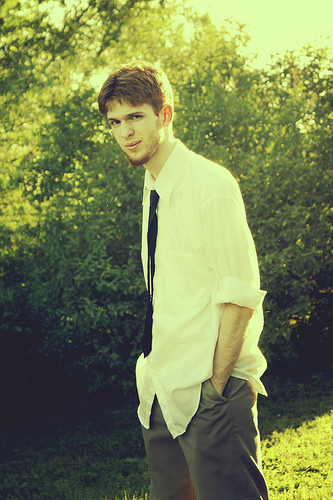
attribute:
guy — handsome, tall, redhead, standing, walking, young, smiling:
[98, 62, 269, 498]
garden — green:
[0, 0, 332, 500]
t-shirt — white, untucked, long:
[134, 138, 268, 439]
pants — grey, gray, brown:
[139, 376, 268, 500]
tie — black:
[142, 190, 160, 358]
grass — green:
[1, 375, 331, 499]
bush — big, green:
[229, 48, 332, 364]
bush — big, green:
[2, 19, 316, 395]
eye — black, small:
[131, 114, 143, 121]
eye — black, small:
[112, 118, 120, 125]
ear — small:
[161, 104, 173, 127]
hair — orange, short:
[98, 62, 173, 117]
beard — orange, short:
[118, 116, 162, 165]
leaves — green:
[1, 1, 167, 139]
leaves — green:
[0, 0, 251, 175]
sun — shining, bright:
[250, 0, 332, 50]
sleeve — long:
[201, 193, 267, 311]